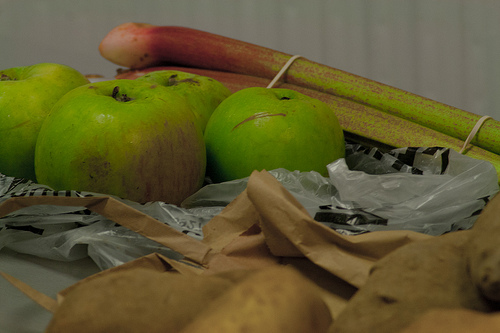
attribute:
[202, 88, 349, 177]
apple — green, large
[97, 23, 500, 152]
fruit — long, bundled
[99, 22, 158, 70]
end — pink, red, white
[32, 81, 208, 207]
apple — bruised, green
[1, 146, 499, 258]
bags — platic, plastic, clear, white, black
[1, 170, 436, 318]
bag — paper, brown, crinkled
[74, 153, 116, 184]
spot — brown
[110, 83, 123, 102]
stem — small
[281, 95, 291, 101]
stem — small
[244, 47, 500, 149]
stalk — green, red